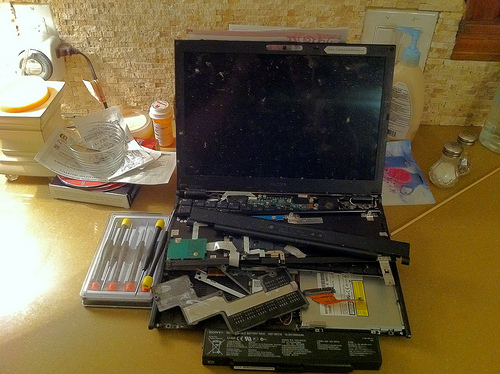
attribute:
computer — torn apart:
[165, 37, 396, 211]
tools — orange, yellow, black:
[109, 217, 156, 294]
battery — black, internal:
[204, 327, 384, 369]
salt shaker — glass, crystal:
[426, 144, 467, 188]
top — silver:
[441, 139, 461, 162]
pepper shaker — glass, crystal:
[449, 131, 478, 154]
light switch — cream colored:
[368, 10, 400, 43]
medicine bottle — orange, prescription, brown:
[147, 97, 174, 145]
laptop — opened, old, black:
[158, 27, 421, 330]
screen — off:
[184, 55, 378, 177]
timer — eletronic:
[18, 47, 53, 79]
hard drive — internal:
[229, 281, 296, 322]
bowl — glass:
[70, 125, 131, 170]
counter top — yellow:
[456, 200, 482, 214]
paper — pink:
[390, 167, 406, 184]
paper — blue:
[391, 147, 408, 164]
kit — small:
[118, 221, 155, 267]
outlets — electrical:
[22, 7, 53, 37]